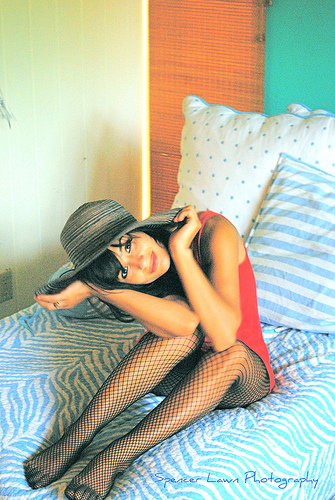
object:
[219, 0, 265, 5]
wood blind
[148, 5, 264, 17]
wood blind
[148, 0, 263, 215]
window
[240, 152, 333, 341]
blue pillow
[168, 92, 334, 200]
white pillow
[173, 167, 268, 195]
pillow case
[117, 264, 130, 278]
eye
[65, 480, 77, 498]
toe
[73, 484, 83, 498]
toe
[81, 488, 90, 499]
toe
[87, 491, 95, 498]
toe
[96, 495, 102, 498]
toe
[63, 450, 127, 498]
foot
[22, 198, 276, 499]
girl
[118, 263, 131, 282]
right eye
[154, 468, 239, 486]
name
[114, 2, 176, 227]
corner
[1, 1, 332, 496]
bedroom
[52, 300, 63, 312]
ring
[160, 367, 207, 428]
hose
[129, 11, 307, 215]
wall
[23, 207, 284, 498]
woman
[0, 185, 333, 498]
bed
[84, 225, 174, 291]
woman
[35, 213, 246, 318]
girl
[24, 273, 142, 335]
hand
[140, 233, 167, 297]
mouth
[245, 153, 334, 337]
pillow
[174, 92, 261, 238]
pillow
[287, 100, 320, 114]
pillow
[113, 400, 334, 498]
bed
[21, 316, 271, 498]
fishnet stockings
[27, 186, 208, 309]
hat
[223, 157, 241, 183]
dots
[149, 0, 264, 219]
blind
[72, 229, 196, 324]
hair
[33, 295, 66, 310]
finger